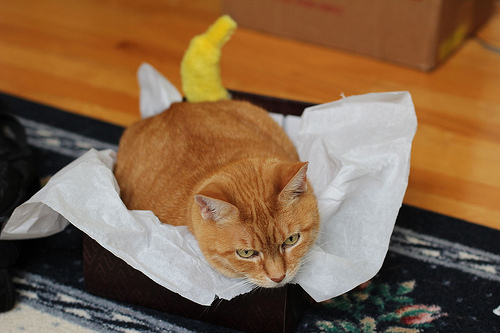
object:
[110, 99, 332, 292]
cat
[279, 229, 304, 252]
eyes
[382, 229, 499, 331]
rug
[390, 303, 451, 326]
flowers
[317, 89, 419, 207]
paper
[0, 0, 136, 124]
floor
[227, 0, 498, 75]
box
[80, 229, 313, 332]
box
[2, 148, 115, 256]
tissue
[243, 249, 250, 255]
dot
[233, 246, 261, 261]
eye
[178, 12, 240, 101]
toy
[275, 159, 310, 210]
ears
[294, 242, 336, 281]
whiskers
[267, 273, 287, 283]
nose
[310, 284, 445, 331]
pattern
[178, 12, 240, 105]
banana